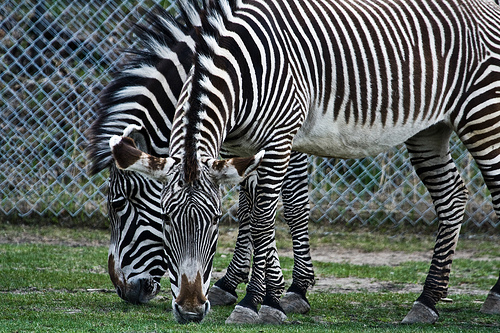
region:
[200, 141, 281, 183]
an ear on a zebra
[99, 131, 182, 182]
an ear on a zebra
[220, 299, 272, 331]
a hoof on a zebra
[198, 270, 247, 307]
a hoof on a zebra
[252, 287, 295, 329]
a hoof on a zebra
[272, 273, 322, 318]
a hoof on a zebra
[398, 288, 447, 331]
a hoof on a zebra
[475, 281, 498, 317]
a hoof on a zebra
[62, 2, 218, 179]
black and white zebra mane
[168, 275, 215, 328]
large nose on a zebra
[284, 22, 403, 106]
black and white stripes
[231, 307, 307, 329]
sturdy gray hooves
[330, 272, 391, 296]
a patch of gray dirt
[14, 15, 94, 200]
a silver metal wire fence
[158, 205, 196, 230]
the eye of a zebra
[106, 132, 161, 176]
a pointy ear on a head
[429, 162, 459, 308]
a hind leg of a zebra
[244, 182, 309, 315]
fore legs of a zebra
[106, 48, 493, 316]
two zebras grazing on green grass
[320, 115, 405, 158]
a the white stomach of a zebra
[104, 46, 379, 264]
A zebra is visible.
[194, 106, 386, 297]
A zebra is visible.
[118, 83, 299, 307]
A zebra is visible.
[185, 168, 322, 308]
A zebra is visible.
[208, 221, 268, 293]
A zebra is visible.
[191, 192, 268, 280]
A zebra is visible.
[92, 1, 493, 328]
the zebras are black and white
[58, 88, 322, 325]
zebras are eating grass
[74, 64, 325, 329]
zebra's heads are down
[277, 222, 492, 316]
the grass is patchy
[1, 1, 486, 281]
metal fence behind zebras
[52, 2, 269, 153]
hair on zebra's neck is black and white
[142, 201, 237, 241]
zebra's eyes are black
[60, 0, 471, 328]
zebras are standing next to each other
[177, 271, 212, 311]
brown spot above nose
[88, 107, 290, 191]
brown spots on ears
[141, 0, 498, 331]
a zebra in the picture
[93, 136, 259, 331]
the head of a zebra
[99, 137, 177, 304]
the head of a zebra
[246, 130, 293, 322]
the leg of a zebra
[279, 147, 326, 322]
the leg of a zebra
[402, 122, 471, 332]
the leg of a zebra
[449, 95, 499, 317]
the leg of a zebra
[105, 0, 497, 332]
the zebra is black and white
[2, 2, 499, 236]
barbed wire fence at the background